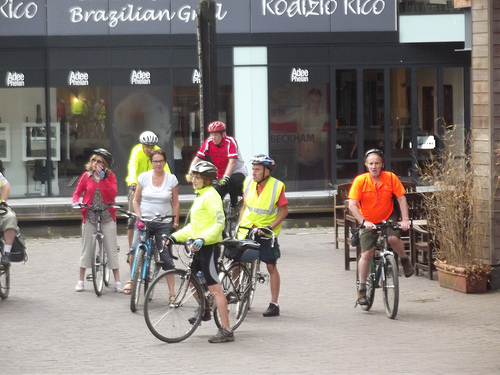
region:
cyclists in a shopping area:
[6, 3, 484, 360]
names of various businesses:
[0, 0, 395, 30]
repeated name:
[0, 62, 200, 83]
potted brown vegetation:
[427, 156, 487, 291]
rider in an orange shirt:
[345, 145, 411, 320]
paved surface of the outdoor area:
[6, 345, 442, 370]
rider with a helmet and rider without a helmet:
[125, 125, 177, 226]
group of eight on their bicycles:
[0, 105, 415, 350]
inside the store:
[0, 90, 195, 130]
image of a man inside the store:
[271, 85, 333, 166]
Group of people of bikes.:
[0, 120, 426, 337]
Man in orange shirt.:
[345, 140, 410, 310]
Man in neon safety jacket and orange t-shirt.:
[235, 153, 291, 315]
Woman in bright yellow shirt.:
[170, 160, 241, 355]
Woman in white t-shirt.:
[130, 150, 181, 307]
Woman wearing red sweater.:
[61, 142, 126, 300]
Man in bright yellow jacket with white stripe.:
[125, 130, 178, 266]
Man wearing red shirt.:
[191, 105, 251, 220]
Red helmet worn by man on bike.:
[201, 115, 232, 130]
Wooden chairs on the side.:
[327, 175, 462, 276]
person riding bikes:
[9, 108, 429, 356]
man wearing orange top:
[339, 132, 416, 327]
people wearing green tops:
[171, 145, 293, 342]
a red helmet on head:
[199, 115, 231, 155]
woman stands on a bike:
[63, 142, 128, 305]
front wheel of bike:
[135, 260, 210, 341]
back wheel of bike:
[210, 256, 255, 331]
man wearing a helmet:
[239, 145, 285, 200]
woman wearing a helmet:
[182, 152, 224, 210]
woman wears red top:
[64, 142, 131, 239]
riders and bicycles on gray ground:
[3, 230, 493, 370]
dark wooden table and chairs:
[335, 175, 465, 270]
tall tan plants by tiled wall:
[426, 5, 491, 290]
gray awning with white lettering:
[5, 0, 390, 40]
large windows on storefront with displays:
[0, 35, 325, 190]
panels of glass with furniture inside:
[325, 60, 456, 180]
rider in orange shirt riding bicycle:
[345, 145, 415, 316]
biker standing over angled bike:
[141, 156, 251, 341]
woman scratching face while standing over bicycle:
[70, 150, 125, 295]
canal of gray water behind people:
[17, 207, 330, 234]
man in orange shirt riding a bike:
[346, 143, 413, 321]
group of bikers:
[1, 116, 413, 348]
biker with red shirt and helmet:
[187, 115, 247, 195]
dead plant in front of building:
[421, 120, 489, 296]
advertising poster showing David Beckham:
[265, 84, 334, 183]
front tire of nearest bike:
[140, 264, 205, 345]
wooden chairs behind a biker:
[323, 174, 449, 276]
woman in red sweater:
[72, 145, 124, 295]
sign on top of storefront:
[0, 3, 409, 62]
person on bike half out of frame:
[0, 165, 28, 302]